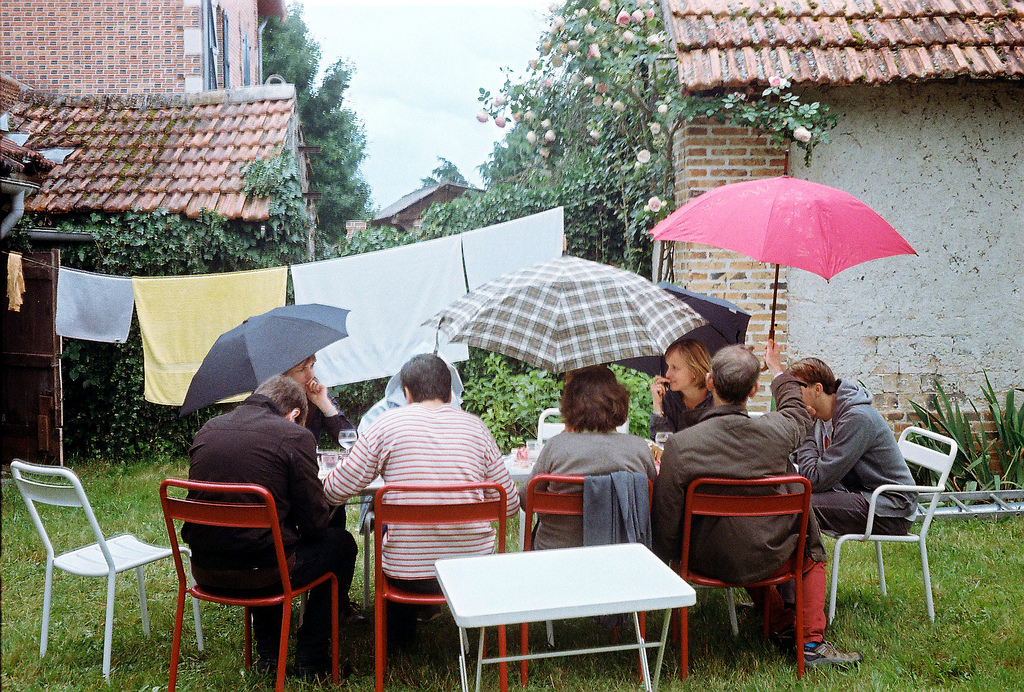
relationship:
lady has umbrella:
[502, 362, 689, 565] [435, 251, 692, 381]